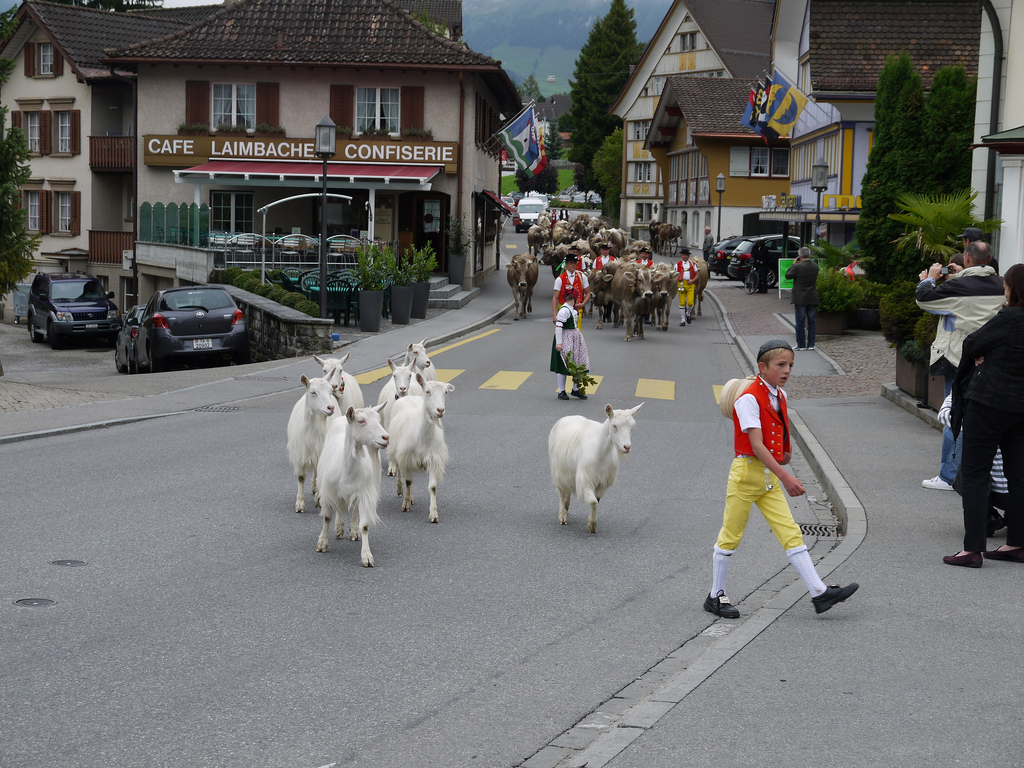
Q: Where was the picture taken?
A: On a city street.